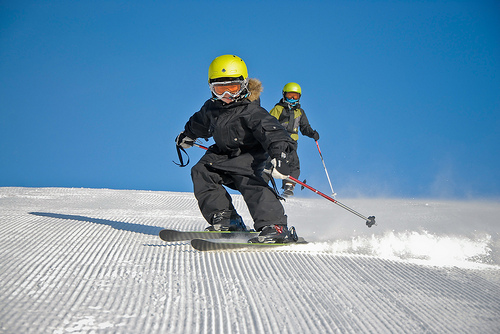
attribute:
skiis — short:
[153, 225, 308, 252]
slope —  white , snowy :
[1, 184, 496, 331]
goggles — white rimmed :
[207, 80, 243, 97]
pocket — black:
[258, 112, 285, 138]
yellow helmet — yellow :
[202, 49, 259, 81]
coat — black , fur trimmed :
[168, 92, 304, 191]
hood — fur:
[241, 78, 265, 103]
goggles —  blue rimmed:
[283, 91, 300, 100]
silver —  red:
[337, 201, 367, 220]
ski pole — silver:
[265, 156, 377, 226]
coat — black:
[178, 109, 292, 174]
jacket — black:
[162, 100, 293, 176]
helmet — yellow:
[195, 40, 260, 82]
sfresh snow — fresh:
[286, 227, 498, 273]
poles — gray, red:
[271, 170, 356, 212]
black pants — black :
[181, 144, 296, 231]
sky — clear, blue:
[6, 1, 492, 199]